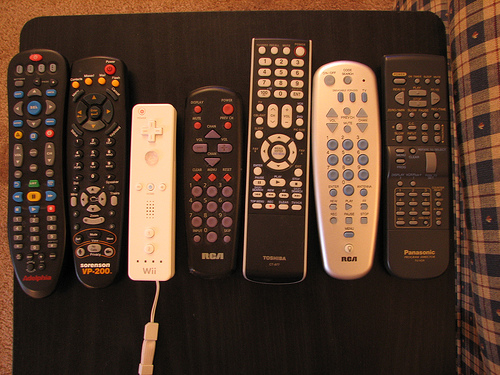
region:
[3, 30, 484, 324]
An assortment of remotes sitting on a tray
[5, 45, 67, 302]
An Adelphia remote used for cable television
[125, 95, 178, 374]
A remote used to play WII games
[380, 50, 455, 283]
A Panasonic remote with buttons in shades of brown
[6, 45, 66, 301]
Remote with some buttons in bright colors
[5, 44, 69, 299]
Colored buttons for selection of various channel and video movements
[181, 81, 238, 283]
A basic remote made by RCA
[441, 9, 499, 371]
Checkered pattern on a piece of furniture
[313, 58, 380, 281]
A basic white RCA remote with buttons of varying shades of gray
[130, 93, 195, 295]
Wii controller is white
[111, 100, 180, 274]
Wii controller is white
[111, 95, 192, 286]
Wii controller is white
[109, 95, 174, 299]
Wii controller is white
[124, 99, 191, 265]
Wii controller is white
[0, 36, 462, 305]
remote controllers are lined-up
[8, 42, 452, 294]
remote controllers are lined-up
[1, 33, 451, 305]
remote controllers are lined-up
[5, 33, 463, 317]
remote controllers are lined-up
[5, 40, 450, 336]
remote controllers are lined-up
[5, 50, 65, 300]
a black remote control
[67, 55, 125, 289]
a black remote control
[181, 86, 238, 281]
a black remote control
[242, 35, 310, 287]
a black remote control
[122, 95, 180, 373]
A white game controller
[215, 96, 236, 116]
A round red button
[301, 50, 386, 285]
Gray remote control with blue buttons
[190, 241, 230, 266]
"RCA" written on remote control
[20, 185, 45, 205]
A round yellow button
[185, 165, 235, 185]
A row of three red buttons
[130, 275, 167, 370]
White strap of a controller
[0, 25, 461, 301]
A row of seven remote controls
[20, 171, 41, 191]
A tiny green button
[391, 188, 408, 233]
button on a remote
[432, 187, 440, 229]
button on a remote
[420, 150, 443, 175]
button on a remote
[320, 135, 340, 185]
button on a remote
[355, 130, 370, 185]
button on a remote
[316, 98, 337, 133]
button on a remote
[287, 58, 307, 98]
button on a remote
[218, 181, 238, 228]
button on a remote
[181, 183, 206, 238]
button on a remote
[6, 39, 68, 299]
A long black controller.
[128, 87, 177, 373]
A white gaming controller.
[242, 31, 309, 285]
A back controller with white buttons.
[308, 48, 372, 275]
A silver television controller.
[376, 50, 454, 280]
A black controller with gray buttons.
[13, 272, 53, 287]
Red lettering on a black controller.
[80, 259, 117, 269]
White lettering on a black controller.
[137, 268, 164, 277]
Gray lettering on a white controller.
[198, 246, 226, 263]
Gray lettering on a black controller.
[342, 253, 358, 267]
Black lettering on a silver controller.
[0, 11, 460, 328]
remote controls are on a table top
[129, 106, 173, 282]
the remote is for a Wii gaming console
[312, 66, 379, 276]
the remote is grey